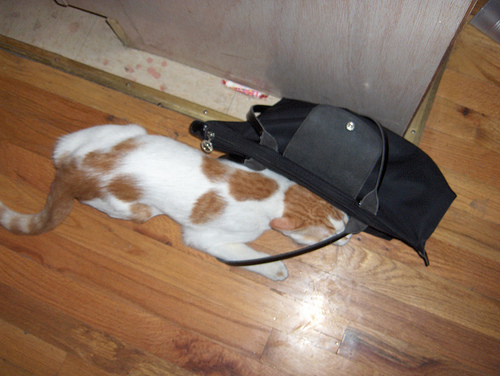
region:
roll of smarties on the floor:
[213, 65, 276, 103]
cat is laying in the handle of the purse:
[51, 140, 384, 284]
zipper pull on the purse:
[198, 133, 217, 169]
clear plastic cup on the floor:
[476, 0, 498, 44]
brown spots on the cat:
[185, 150, 289, 225]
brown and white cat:
[38, 118, 354, 272]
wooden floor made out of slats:
[3, 26, 494, 368]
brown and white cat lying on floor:
[0, 120, 347, 280]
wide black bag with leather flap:
[186, 80, 453, 265]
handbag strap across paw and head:
[205, 147, 375, 262]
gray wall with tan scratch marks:
[57, 1, 472, 136]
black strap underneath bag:
[240, 85, 386, 215]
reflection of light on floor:
[220, 250, 370, 371]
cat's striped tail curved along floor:
[0, 146, 85, 236]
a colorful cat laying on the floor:
[3, 125, 359, 295]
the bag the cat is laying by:
[188, 95, 460, 278]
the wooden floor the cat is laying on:
[6, 58, 496, 374]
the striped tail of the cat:
[3, 183, 68, 238]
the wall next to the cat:
[7, 2, 457, 137]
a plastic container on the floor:
[469, 2, 499, 44]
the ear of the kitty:
[266, 214, 296, 232]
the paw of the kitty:
[232, 245, 285, 285]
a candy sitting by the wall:
[215, 65, 266, 102]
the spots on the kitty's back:
[190, 155, 268, 238]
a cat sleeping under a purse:
[0, 70, 472, 305]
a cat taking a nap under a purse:
[2, 63, 499, 304]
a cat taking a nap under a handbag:
[6, 49, 486, 346]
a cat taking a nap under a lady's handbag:
[4, 32, 499, 304]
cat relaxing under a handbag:
[2, 56, 474, 309]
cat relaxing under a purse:
[2, 59, 489, 308]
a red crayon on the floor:
[215, 67, 275, 102]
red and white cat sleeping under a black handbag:
[2, 84, 478, 340]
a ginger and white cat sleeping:
[0, 87, 382, 284]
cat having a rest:
[2, 53, 487, 320]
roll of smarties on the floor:
[211, 58, 288, 123]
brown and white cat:
[35, 112, 369, 299]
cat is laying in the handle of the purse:
[188, 173, 356, 265]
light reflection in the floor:
[283, 270, 353, 356]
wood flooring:
[16, 266, 228, 365]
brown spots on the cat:
[191, 142, 281, 235]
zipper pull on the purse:
[202, 120, 215, 157]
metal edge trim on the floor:
[10, 30, 91, 90]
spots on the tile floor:
[119, 53, 194, 100]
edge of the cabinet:
[56, 0, 136, 65]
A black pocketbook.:
[193, 80, 468, 286]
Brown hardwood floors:
[2, 25, 492, 374]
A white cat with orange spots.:
[9, 114, 359, 301]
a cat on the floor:
[17, 69, 347, 329]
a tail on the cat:
[1, 168, 76, 262]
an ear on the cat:
[271, 211, 305, 241]